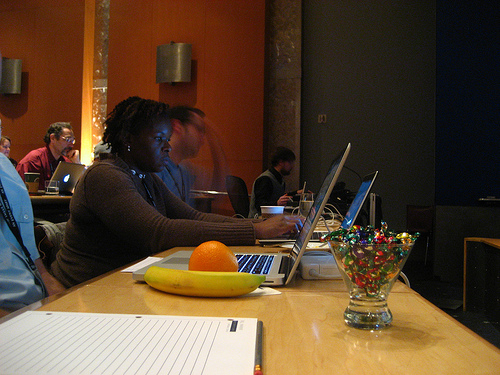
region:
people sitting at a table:
[1, 94, 471, 374]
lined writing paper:
[2, 310, 265, 374]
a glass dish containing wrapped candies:
[328, 218, 423, 332]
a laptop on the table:
[135, 126, 355, 327]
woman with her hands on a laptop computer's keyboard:
[51, 97, 378, 259]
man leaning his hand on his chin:
[21, 118, 86, 198]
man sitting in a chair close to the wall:
[220, 130, 314, 210]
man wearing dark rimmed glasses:
[166, 102, 213, 164]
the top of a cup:
[253, 198, 285, 223]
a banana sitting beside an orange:
[141, 235, 266, 310]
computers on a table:
[185, 87, 397, 358]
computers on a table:
[212, 114, 313, 249]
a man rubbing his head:
[158, 82, 238, 217]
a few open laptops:
[238, 155, 389, 300]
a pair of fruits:
[129, 232, 272, 309]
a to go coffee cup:
[18, 164, 48, 205]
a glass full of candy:
[325, 210, 432, 352]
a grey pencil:
[246, 312, 266, 373]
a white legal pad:
[2, 296, 268, 372]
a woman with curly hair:
[46, 84, 305, 291]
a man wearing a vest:
[246, 130, 299, 220]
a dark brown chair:
[383, 198, 438, 266]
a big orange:
[190, 240, 241, 270]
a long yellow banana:
[140, 265, 265, 292]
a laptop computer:
[46, 156, 83, 191]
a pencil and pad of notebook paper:
[0, 290, 266, 372]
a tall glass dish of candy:
[330, 220, 415, 332]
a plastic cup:
[258, 201, 279, 216]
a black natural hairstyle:
[101, 93, 171, 160]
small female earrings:
[125, 141, 130, 149]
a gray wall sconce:
[150, 37, 195, 82]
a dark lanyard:
[0, 180, 40, 272]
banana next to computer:
[143, 263, 268, 297]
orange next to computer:
[185, 239, 240, 276]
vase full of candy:
[323, 220, 421, 328]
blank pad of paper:
[0, 310, 255, 372]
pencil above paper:
[253, 317, 265, 372]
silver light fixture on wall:
[153, 37, 198, 90]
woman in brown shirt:
[51, 96, 304, 286]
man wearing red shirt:
[14, 121, 81, 186]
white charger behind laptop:
[299, 247, 347, 283]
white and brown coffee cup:
[259, 204, 285, 218]